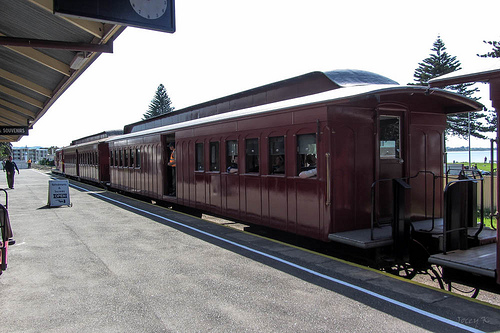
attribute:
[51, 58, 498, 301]
train — long, maroon, burgundy, red, metal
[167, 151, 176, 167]
vest — orange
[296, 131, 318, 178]
window — rectangular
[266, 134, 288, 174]
window — rectangular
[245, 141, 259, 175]
window — rectangular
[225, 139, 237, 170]
window — rectangular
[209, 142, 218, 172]
window — rectangular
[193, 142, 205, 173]
window — rectangular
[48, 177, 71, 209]
sign — white, black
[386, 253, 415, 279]
wheel — black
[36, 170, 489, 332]
lines — white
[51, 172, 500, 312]
line — yellow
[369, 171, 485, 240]
rail — metal, black, safty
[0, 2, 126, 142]
awning — black, gold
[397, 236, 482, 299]
cable — black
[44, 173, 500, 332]
paint — white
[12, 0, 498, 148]
sky — cloudy